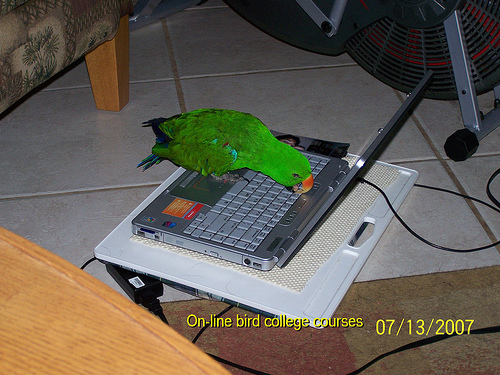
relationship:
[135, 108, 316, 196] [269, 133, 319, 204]
bird has a head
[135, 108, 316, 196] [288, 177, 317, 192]
bird has a beak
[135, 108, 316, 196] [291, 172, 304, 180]
bird has an eye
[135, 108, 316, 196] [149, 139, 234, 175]
bird has a wing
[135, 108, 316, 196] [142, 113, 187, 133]
bird has a tail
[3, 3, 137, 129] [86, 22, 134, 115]
chair has a leg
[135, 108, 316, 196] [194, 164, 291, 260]
bird on keyboard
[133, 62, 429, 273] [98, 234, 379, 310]
laptop on a tray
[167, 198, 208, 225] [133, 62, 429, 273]
label on laptop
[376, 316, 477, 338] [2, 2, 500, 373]
date on picture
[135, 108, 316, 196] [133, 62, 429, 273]
bird on a laptop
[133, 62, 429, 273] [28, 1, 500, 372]
laptop on floor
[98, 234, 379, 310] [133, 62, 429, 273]
tray has a laptop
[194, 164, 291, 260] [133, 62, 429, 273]
keyboard on laptop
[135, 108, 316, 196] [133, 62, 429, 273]
bird pecking at laptop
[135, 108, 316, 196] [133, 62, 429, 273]
bird trying to eat laptop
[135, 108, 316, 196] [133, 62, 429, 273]
bird sitting on laptop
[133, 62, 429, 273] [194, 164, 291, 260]
laptop with a keyboard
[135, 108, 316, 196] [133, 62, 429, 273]
bird sitting on a laptop